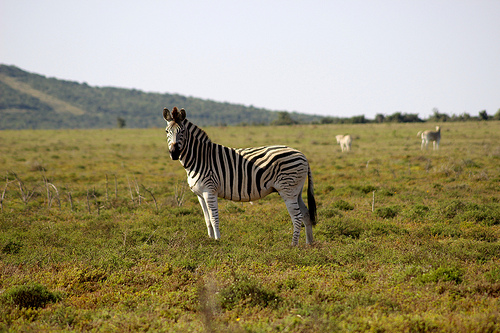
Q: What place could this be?
A: It is a field.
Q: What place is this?
A: It is a field.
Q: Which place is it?
A: It is a field.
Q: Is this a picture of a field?
A: Yes, it is showing a field.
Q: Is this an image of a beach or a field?
A: It is showing a field.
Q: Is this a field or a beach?
A: It is a field.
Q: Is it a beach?
A: No, it is a field.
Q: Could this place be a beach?
A: No, it is a field.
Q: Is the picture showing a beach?
A: No, the picture is showing a field.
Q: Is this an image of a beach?
A: No, the picture is showing a field.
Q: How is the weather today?
A: It is cloudless.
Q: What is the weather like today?
A: It is cloudless.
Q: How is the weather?
A: It is cloudless.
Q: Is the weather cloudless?
A: Yes, it is cloudless.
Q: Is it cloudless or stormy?
A: It is cloudless.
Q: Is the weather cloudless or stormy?
A: It is cloudless.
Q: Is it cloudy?
A: No, it is cloudless.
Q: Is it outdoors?
A: Yes, it is outdoors.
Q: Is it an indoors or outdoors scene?
A: It is outdoors.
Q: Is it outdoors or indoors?
A: It is outdoors.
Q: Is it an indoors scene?
A: No, it is outdoors.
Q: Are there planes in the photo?
A: No, there are no planes.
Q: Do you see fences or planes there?
A: No, there are no planes or fences.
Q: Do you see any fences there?
A: No, there are no fences.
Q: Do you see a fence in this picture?
A: No, there are no fences.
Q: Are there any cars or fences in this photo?
A: No, there are no fences or cars.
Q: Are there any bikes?
A: No, there are no bikes.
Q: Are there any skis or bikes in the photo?
A: No, there are no bikes or skis.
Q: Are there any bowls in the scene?
A: No, there are no bowls.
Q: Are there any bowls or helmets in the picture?
A: No, there are no bowls or helmets.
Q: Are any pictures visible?
A: No, there are no pictures.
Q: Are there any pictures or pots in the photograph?
A: No, there are no pictures or pots.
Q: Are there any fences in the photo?
A: No, there are no fences.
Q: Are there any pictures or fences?
A: No, there are no fences or pictures.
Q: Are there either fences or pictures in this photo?
A: No, there are no fences or pictures.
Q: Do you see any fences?
A: No, there are no fences.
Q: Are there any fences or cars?
A: No, there are no fences or cars.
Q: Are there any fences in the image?
A: No, there are no fences.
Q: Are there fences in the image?
A: No, there are no fences.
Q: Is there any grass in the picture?
A: Yes, there is grass.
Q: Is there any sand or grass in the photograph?
A: Yes, there is grass.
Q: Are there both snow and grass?
A: No, there is grass but no snow.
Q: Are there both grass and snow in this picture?
A: No, there is grass but no snow.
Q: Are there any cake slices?
A: No, there are no cake slices.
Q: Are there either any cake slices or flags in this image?
A: No, there are no cake slices or flags.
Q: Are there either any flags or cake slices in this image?
A: No, there are no cake slices or flags.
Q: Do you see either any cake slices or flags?
A: No, there are no cake slices or flags.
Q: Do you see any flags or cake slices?
A: No, there are no cake slices or flags.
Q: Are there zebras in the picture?
A: Yes, there is a zebra.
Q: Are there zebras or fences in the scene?
A: Yes, there is a zebra.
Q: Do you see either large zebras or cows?
A: Yes, there is a large zebra.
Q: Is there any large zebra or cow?
A: Yes, there is a large zebra.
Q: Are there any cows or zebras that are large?
A: Yes, the zebra is large.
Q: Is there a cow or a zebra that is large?
A: Yes, the zebra is large.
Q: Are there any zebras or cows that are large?
A: Yes, the zebra is large.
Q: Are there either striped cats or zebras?
A: Yes, there is a striped zebra.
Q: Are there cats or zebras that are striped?
A: Yes, the zebra is striped.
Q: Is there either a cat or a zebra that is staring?
A: Yes, the zebra is staring.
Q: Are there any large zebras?
A: Yes, there is a large zebra.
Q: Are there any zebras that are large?
A: Yes, there is a zebra that is large.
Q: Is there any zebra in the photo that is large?
A: Yes, there is a zebra that is large.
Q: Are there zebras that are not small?
A: Yes, there is a large zebra.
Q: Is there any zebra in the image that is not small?
A: Yes, there is a large zebra.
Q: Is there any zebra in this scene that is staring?
A: Yes, there is a zebra that is staring.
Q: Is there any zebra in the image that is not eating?
A: Yes, there is a zebra that is staring.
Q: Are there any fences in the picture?
A: No, there are no fences.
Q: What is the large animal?
A: The animal is a zebra.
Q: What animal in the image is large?
A: The animal is a zebra.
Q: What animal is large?
A: The animal is a zebra.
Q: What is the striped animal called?
A: The animal is a zebra.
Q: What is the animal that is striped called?
A: The animal is a zebra.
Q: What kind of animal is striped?
A: The animal is a zebra.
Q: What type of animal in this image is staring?
A: The animal is a zebra.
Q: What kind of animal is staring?
A: The animal is a zebra.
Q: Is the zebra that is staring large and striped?
A: Yes, the zebra is large and striped.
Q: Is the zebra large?
A: Yes, the zebra is large.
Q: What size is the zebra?
A: The zebra is large.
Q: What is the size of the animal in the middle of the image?
A: The zebra is large.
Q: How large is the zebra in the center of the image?
A: The zebra is large.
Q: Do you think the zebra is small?
A: No, the zebra is large.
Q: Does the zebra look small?
A: No, the zebra is large.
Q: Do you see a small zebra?
A: No, there is a zebra but it is large.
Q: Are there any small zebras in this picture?
A: No, there is a zebra but it is large.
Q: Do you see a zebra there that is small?
A: No, there is a zebra but it is large.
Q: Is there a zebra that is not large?
A: No, there is a zebra but it is large.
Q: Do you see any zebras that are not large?
A: No, there is a zebra but it is large.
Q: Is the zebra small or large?
A: The zebra is large.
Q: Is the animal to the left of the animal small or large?
A: The zebra is large.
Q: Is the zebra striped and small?
A: No, the zebra is striped but large.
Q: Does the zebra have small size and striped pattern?
A: No, the zebra is striped but large.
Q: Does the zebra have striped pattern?
A: Yes, the zebra is striped.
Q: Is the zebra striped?
A: Yes, the zebra is striped.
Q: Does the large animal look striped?
A: Yes, the zebra is striped.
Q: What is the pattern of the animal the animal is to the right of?
A: The zebra is striped.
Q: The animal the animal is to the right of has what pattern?
A: The zebra is striped.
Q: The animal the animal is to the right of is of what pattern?
A: The zebra is striped.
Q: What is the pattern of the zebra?
A: The zebra is striped.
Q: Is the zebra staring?
A: Yes, the zebra is staring.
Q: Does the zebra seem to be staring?
A: Yes, the zebra is staring.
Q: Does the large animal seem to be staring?
A: Yes, the zebra is staring.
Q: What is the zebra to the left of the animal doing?
A: The zebra is staring.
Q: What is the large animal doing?
A: The zebra is staring.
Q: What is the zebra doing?
A: The zebra is staring.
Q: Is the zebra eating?
A: No, the zebra is staring.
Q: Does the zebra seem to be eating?
A: No, the zebra is staring.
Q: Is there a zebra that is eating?
A: No, there is a zebra but it is staring.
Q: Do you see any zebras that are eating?
A: No, there is a zebra but it is staring.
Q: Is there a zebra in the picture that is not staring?
A: No, there is a zebra but it is staring.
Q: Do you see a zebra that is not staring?
A: No, there is a zebra but it is staring.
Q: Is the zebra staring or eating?
A: The zebra is staring.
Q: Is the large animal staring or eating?
A: The zebra is staring.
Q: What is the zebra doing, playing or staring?
A: The zebra is staring.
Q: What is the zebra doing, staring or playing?
A: The zebra is staring.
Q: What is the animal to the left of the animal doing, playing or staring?
A: The zebra is staring.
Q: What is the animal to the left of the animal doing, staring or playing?
A: The zebra is staring.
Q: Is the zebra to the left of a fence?
A: No, the zebra is to the left of the animal.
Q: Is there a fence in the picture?
A: No, there are no fences.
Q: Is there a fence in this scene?
A: No, there are no fences.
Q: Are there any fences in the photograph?
A: No, there are no fences.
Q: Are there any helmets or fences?
A: No, there are no fences or helmets.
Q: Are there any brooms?
A: No, there are no brooms.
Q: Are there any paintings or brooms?
A: No, there are no brooms or paintings.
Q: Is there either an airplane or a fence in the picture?
A: No, there are no fences or airplanes.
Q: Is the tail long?
A: Yes, the tail is long.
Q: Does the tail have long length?
A: Yes, the tail is long.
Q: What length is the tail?
A: The tail is long.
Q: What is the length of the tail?
A: The tail is long.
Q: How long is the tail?
A: The tail is long.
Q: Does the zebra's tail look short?
A: No, the tail is long.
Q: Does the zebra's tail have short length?
A: No, the tail is long.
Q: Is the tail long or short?
A: The tail is long.